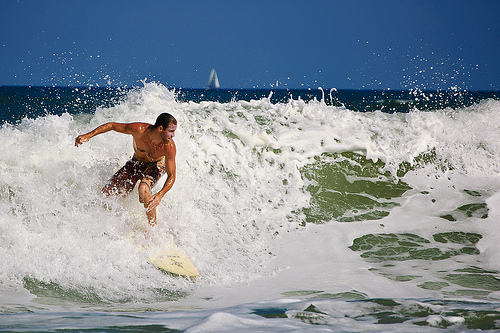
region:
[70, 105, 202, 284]
Surfer in water surfing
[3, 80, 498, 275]
Big wave in water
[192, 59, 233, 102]
Sailboat in the distance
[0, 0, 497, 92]
Clear bright blue sky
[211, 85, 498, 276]
The waves are white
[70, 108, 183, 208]
Surfer isn't wearing shirt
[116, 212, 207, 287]
The surfboard is yellow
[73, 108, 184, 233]
Surfer is wearing black shorts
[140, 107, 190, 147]
Man has short hair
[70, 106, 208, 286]
Man is balancing on surfboard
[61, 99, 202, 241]
shirtless man surfing in ocean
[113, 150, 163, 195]
man wearing tan shorts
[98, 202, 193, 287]
man surfing on tan board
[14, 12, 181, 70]
clear blue sky above ocean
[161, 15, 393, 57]
clear blue sky above ocean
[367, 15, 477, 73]
clear blue sky above ocean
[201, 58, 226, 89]
white sail boat in blue ocean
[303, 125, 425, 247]
green and white ocean surf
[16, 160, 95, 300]
green and white ocean surf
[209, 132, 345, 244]
green and white ocean surf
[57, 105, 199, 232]
young man surfing in ocean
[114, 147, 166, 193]
young man wearing shorts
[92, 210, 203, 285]
young man on tan surf board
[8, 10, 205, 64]
clear blue cloudless sky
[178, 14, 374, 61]
clear blue cloudless sky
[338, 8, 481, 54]
clear blue cloudless sky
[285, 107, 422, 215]
green and white ocean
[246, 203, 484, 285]
green and white ocean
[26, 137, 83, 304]
green and white ocean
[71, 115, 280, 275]
man is riding wave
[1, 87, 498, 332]
Entire body of water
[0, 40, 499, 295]
White spray from the wave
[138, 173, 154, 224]
Surfer's bare left leg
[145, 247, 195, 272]
Tip of the surfboard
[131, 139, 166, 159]
Surfer's bare chest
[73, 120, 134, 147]
Surfer's extended right arm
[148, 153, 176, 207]
Surfer's left arm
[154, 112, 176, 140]
Surfer's entire head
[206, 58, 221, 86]
Tiny sailboat in the background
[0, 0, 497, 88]
Clear blue sky in the background